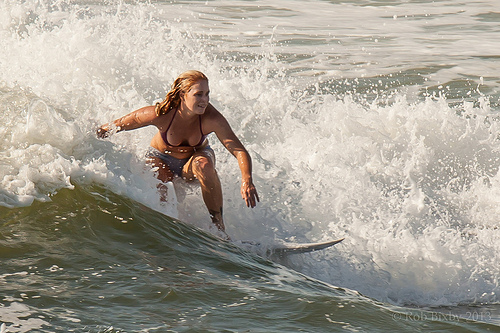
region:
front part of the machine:
[286, 213, 361, 293]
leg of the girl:
[198, 158, 242, 238]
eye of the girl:
[185, 87, 210, 99]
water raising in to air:
[11, 39, 153, 256]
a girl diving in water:
[101, 60, 312, 260]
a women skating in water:
[63, 46, 335, 279]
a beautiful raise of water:
[33, 25, 137, 233]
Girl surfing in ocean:
[95, 69, 263, 246]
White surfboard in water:
[235, 238, 342, 253]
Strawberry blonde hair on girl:
[160, 69, 201, 112]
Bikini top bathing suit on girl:
[157, 113, 203, 147]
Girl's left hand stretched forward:
[240, 183, 260, 207]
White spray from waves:
[270, 83, 498, 286]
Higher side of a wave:
[25, 185, 474, 330]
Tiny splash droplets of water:
[378, 10, 440, 25]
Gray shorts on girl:
[141, 145, 218, 171]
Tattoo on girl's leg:
[210, 205, 225, 223]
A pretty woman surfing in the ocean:
[9, 1, 495, 328]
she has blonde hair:
[141, 68, 223, 121]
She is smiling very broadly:
[162, 72, 223, 115]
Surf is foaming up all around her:
[4, 10, 499, 302]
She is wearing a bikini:
[145, 116, 222, 176]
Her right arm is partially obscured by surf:
[38, 95, 158, 150]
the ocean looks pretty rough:
[2, 5, 499, 323]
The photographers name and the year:
[389, 298, 495, 325]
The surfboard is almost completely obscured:
[93, 178, 369, 282]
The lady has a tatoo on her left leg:
[193, 195, 246, 250]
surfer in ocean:
[80, 53, 255, 258]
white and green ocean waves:
[68, 253, 140, 303]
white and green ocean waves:
[180, 266, 220, 304]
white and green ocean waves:
[68, 115, 118, 183]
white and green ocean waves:
[300, 32, 330, 66]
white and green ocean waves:
[397, 29, 459, 104]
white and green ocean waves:
[45, 213, 140, 275]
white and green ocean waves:
[311, 18, 441, 90]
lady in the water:
[113, 75, 264, 238]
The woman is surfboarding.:
[129, 77, 359, 270]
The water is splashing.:
[241, 79, 463, 214]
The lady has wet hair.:
[163, 68, 190, 115]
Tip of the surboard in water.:
[250, 219, 350, 261]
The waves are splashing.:
[18, 103, 482, 265]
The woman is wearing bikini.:
[153, 125, 218, 176]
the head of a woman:
[157, 63, 212, 121]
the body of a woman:
[118, 100, 218, 164]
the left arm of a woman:
[206, 110, 271, 210]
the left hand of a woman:
[238, 177, 270, 211]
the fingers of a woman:
[242, 199, 269, 209]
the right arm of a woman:
[90, 110, 162, 145]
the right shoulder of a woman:
[142, 96, 175, 128]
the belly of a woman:
[150, 142, 215, 166]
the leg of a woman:
[182, 156, 250, 234]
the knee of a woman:
[190, 158, 233, 185]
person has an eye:
[205, 93, 209, 99]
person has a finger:
[254, 189, 260, 201]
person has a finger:
[250, 190, 255, 204]